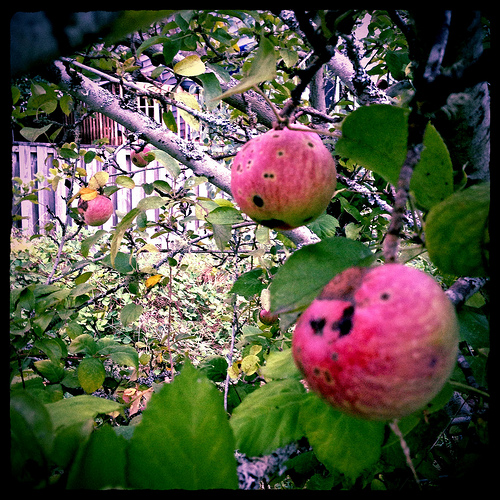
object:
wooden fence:
[9, 139, 234, 240]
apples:
[74, 121, 460, 418]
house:
[76, 10, 222, 145]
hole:
[252, 195, 264, 209]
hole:
[309, 303, 356, 338]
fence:
[11, 142, 232, 239]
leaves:
[10, 261, 152, 392]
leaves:
[23, 7, 492, 355]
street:
[225, 107, 315, 209]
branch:
[81, 160, 167, 190]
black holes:
[251, 194, 264, 210]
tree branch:
[39, 10, 435, 267]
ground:
[421, 141, 449, 185]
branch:
[51, 59, 326, 248]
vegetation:
[117, 271, 194, 335]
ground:
[138, 257, 272, 398]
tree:
[3, 0, 489, 493]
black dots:
[288, 262, 462, 420]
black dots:
[229, 127, 337, 228]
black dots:
[77, 194, 113, 227]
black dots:
[129, 147, 150, 168]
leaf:
[0, 352, 388, 493]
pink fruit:
[290, 260, 455, 421]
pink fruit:
[231, 126, 334, 228]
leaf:
[68, 334, 140, 394]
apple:
[290, 261, 459, 420]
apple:
[228, 129, 337, 233]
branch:
[242, 0, 381, 126]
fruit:
[258, 308, 278, 325]